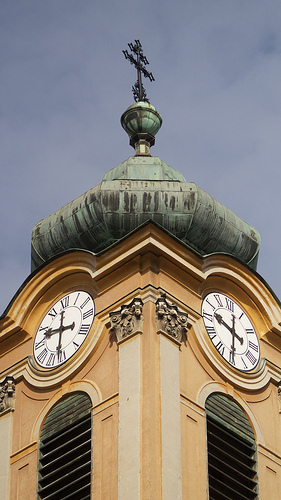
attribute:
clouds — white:
[17, 15, 42, 38]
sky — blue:
[1, 4, 278, 272]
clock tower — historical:
[0, 38, 280, 498]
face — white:
[27, 300, 103, 358]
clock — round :
[28, 290, 102, 378]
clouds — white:
[0, 0, 280, 316]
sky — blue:
[0, 0, 279, 316]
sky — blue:
[151, 14, 280, 182]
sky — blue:
[0, 0, 119, 157]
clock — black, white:
[30, 288, 95, 368]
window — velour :
[32, 389, 90, 498]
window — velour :
[29, 389, 110, 497]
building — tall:
[7, 32, 280, 498]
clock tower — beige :
[0, 216, 278, 498]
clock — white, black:
[200, 291, 260, 371]